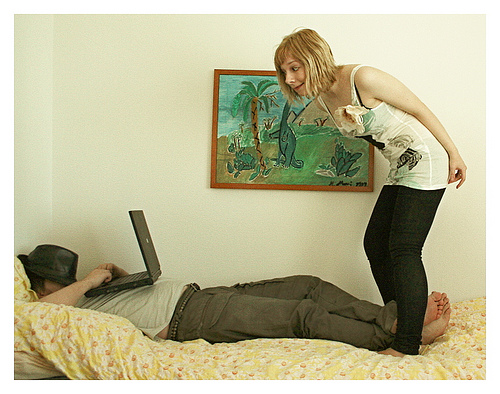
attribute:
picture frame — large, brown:
[200, 65, 377, 197]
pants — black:
[361, 163, 453, 354]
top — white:
[313, 64, 448, 192]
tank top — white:
[341, 92, 492, 229]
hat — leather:
[17, 243, 79, 283]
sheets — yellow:
[56, 283, 313, 390]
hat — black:
[20, 242, 79, 281]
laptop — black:
[92, 215, 169, 299]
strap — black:
[344, 60, 375, 107]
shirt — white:
[309, 67, 452, 188]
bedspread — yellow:
[15, 256, 485, 380]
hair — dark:
[29, 275, 43, 286]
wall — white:
[19, 15, 493, 297]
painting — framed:
[208, 67, 375, 193]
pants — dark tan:
[211, 278, 380, 348]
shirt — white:
[71, 275, 181, 330]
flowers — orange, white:
[130, 346, 191, 382]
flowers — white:
[199, 337, 319, 377]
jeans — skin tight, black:
[364, 186, 444, 353]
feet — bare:
[419, 291, 452, 343]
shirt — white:
[77, 280, 186, 342]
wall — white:
[65, 57, 174, 156]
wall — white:
[60, 36, 182, 156]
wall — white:
[15, 29, 48, 225]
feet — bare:
[419, 281, 458, 348]